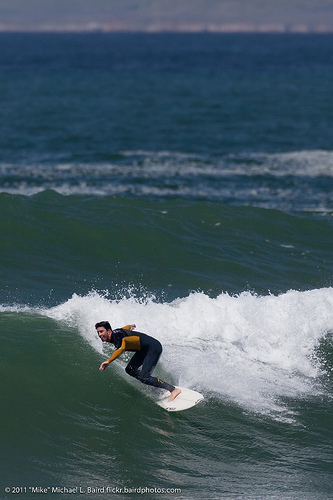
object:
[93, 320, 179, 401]
man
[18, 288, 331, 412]
wave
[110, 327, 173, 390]
wet suit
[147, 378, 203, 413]
surfboard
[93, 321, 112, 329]
hair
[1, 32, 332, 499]
water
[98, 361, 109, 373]
hand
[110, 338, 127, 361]
arm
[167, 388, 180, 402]
feet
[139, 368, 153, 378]
knee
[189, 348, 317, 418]
foam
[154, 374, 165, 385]
logo